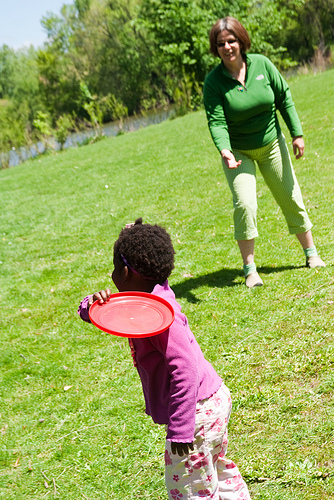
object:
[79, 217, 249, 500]
child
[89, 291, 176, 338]
frisbee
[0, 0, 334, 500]
outside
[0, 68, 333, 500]
grass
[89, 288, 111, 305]
hand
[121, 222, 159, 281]
headband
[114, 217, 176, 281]
hair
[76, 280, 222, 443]
shirt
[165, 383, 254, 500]
pants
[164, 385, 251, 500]
flowers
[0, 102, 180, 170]
water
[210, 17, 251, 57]
hair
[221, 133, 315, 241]
capris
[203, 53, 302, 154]
shirt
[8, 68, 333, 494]
field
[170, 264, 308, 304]
shadow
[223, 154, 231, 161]
finger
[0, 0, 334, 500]
garden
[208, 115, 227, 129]
elbow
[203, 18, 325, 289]
lady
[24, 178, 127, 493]
leaves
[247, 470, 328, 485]
branches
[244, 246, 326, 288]
socks